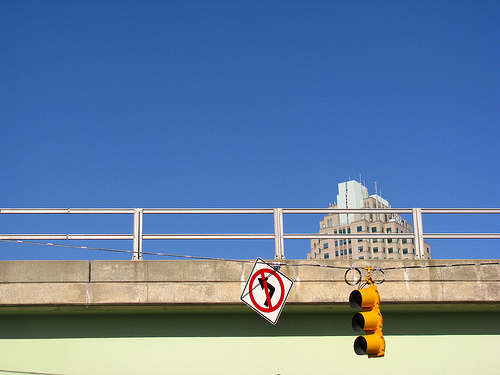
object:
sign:
[238, 256, 299, 328]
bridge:
[0, 205, 500, 374]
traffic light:
[349, 286, 390, 359]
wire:
[1, 239, 500, 270]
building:
[305, 172, 434, 260]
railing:
[0, 207, 500, 216]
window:
[321, 241, 331, 248]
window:
[356, 225, 364, 232]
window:
[370, 226, 378, 233]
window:
[323, 252, 329, 259]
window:
[370, 246, 380, 253]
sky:
[1, 0, 499, 259]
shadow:
[1, 310, 499, 336]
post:
[132, 208, 144, 261]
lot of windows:
[306, 197, 431, 261]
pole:
[374, 179, 377, 196]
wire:
[342, 267, 362, 285]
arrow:
[257, 273, 277, 305]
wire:
[370, 269, 391, 285]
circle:
[244, 266, 287, 314]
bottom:
[348, 334, 389, 358]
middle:
[347, 311, 378, 332]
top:
[345, 288, 376, 309]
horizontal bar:
[1, 204, 500, 214]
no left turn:
[249, 273, 283, 310]